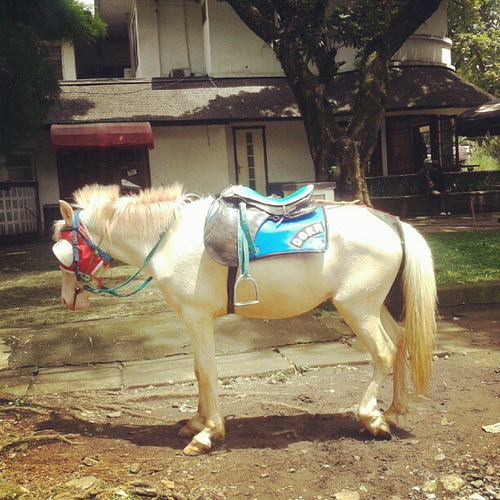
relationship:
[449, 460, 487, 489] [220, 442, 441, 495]
rock on ground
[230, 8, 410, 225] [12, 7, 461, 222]
tree in front of building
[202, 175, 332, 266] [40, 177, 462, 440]
saddle on horse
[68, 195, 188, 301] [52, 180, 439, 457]
harness on horse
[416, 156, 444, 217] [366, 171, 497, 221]
man sitting on bench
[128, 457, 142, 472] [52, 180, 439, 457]
rock laying by horse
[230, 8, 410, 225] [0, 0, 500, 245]
tree in front of building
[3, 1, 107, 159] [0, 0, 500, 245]
tree in front of building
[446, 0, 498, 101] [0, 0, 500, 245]
tree in front of building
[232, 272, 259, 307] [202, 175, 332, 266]
stirrup on saddle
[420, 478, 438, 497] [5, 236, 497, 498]
rock on ground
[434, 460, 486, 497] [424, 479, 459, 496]
rock on ground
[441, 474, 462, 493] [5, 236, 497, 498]
rock on ground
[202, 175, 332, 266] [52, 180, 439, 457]
saddle on horse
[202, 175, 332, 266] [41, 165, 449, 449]
saddle on horse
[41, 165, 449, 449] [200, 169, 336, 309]
horse has saddle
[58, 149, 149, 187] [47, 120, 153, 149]
entrance has awning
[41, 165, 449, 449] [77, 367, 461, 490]
horse on road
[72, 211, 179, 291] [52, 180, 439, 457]
rein on horse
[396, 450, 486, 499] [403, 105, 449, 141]
rocks on ground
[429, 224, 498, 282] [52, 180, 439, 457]
grass behind horse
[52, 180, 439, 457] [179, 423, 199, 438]
horse has hoof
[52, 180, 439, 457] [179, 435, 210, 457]
horse has hoof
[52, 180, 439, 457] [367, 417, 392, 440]
horse has hoof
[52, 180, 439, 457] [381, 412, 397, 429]
horse has hoof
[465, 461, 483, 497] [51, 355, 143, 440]
rock on ground